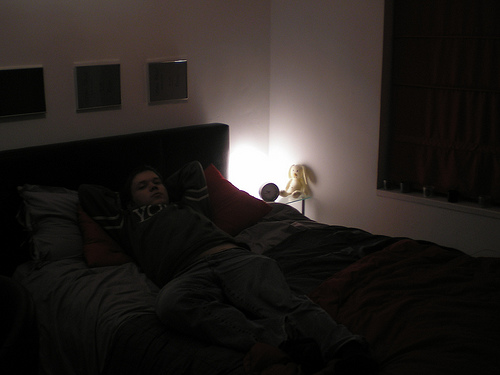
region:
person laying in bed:
[52, 144, 285, 373]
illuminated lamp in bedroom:
[250, 164, 292, 209]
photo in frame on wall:
[134, 49, 201, 116]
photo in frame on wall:
[69, 59, 122, 116]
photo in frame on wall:
[0, 68, 55, 112]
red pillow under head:
[114, 159, 274, 251]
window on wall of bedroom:
[377, 14, 493, 208]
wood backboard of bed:
[2, 114, 227, 201]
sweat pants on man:
[186, 259, 330, 374]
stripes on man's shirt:
[181, 177, 218, 212]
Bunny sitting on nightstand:
[285, 161, 307, 197]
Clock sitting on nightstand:
[259, 182, 280, 202]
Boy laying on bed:
[77, 158, 359, 374]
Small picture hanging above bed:
[146, 57, 191, 109]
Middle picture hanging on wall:
[73, 60, 126, 114]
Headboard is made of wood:
[1, 124, 232, 209]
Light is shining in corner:
[231, 130, 311, 205]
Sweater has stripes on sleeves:
[90, 180, 224, 239]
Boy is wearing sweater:
[73, 162, 245, 284]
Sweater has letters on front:
[131, 199, 184, 226]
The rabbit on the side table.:
[281, 160, 311, 200]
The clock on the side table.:
[260, 180, 280, 202]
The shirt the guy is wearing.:
[86, 157, 232, 264]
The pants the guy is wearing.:
[185, 247, 363, 359]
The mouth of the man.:
[150, 190, 162, 198]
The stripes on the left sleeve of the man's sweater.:
[95, 205, 120, 231]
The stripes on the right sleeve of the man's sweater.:
[176, 185, 208, 197]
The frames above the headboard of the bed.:
[7, 60, 193, 121]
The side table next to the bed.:
[259, 183, 314, 216]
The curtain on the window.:
[393, 7, 495, 204]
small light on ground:
[254, 155, 316, 201]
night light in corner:
[231, 155, 281, 199]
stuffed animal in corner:
[280, 167, 309, 206]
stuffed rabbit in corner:
[278, 161, 310, 206]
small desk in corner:
[271, 193, 308, 214]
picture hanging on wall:
[134, 52, 204, 113]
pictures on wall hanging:
[0, 49, 191, 137]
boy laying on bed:
[65, 142, 300, 332]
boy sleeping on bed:
[100, 163, 260, 344]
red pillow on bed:
[173, 163, 258, 235]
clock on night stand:
[247, 172, 285, 205]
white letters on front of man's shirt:
[125, 198, 195, 229]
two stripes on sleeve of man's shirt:
[177, 179, 213, 208]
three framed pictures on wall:
[2, 51, 197, 132]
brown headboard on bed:
[0, 116, 237, 199]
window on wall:
[362, 2, 495, 222]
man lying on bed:
[52, 160, 374, 370]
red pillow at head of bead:
[177, 160, 284, 240]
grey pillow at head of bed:
[9, 179, 95, 273]